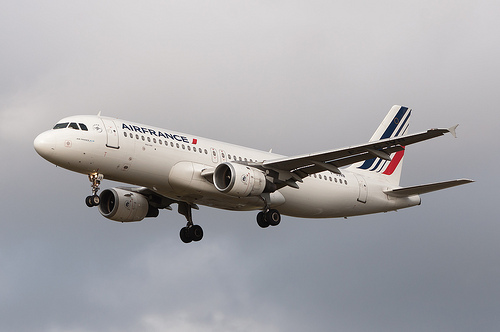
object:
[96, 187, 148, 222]
engine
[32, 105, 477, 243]
airplane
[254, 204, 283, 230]
landing gear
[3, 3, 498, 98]
sky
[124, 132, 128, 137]
window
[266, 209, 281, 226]
black tire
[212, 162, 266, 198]
engine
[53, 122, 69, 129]
windshield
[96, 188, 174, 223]
wing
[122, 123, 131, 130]
letter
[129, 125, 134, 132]
letter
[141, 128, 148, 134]
letter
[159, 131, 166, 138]
letter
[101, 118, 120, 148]
door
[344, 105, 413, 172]
jet tail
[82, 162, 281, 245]
down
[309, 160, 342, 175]
slat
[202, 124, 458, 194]
wing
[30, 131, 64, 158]
nose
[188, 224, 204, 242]
left wheels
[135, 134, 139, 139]
window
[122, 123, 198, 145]
logo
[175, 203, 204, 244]
gear